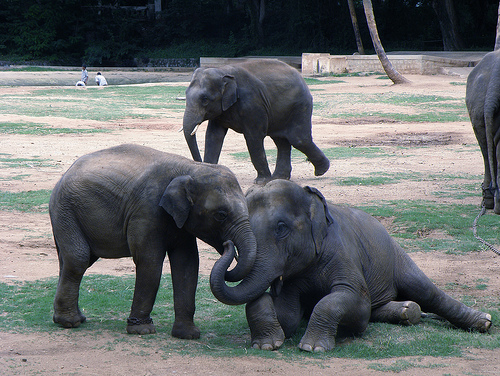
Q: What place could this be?
A: It is a field.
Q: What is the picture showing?
A: It is showing a field.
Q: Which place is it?
A: It is a field.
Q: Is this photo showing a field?
A: Yes, it is showing a field.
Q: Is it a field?
A: Yes, it is a field.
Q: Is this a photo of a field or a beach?
A: It is showing a field.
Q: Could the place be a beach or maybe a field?
A: It is a field.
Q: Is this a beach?
A: No, it is a field.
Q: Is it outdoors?
A: Yes, it is outdoors.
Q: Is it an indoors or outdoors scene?
A: It is outdoors.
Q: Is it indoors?
A: No, it is outdoors.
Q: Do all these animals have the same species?
A: Yes, all the animals are elephants.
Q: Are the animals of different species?
A: No, all the animals are elephants.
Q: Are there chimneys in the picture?
A: No, there are no chimneys.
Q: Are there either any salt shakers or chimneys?
A: No, there are no chimneys or salt shakers.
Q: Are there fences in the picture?
A: No, there are no fences.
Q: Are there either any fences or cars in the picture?
A: No, there are no fences or cars.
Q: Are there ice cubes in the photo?
A: No, there are no ice cubes.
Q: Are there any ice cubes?
A: No, there are no ice cubes.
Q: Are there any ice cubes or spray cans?
A: No, there are no ice cubes or spray cans.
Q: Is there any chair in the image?
A: No, there are no chairs.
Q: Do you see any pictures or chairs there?
A: No, there are no chairs or pictures.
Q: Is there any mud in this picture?
A: Yes, there is mud.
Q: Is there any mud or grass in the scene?
A: Yes, there is mud.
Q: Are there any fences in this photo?
A: No, there are no fences.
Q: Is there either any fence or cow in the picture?
A: No, there are no fences or cows.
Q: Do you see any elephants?
A: Yes, there are elephants.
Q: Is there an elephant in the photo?
A: Yes, there are elephants.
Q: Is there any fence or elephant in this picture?
A: Yes, there are elephants.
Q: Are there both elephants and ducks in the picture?
A: No, there are elephants but no ducks.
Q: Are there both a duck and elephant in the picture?
A: No, there are elephants but no ducks.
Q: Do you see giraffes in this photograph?
A: No, there are no giraffes.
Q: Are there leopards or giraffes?
A: No, there are no giraffes or leopards.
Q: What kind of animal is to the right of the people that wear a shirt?
A: The animals are elephants.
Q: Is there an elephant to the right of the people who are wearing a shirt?
A: Yes, there are elephants to the right of the people.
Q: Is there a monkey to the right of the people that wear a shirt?
A: No, there are elephants to the right of the people.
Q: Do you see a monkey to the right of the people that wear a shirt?
A: No, there are elephants to the right of the people.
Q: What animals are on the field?
A: The animals are elephants.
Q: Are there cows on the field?
A: No, there are elephants on the field.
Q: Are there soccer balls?
A: No, there are no soccer balls.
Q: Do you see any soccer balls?
A: No, there are no soccer balls.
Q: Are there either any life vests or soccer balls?
A: No, there are no soccer balls or life vests.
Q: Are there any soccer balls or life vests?
A: No, there are no soccer balls or life vests.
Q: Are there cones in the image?
A: No, there are no cones.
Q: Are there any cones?
A: No, there are no cones.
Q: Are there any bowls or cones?
A: No, there are no cones or bowls.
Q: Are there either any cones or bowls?
A: No, there are no cones or bowls.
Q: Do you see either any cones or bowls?
A: No, there are no cones or bowls.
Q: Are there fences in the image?
A: No, there are no fences.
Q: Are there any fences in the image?
A: No, there are no fences.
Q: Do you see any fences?
A: No, there are no fences.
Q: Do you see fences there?
A: No, there are no fences.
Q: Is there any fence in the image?
A: No, there are no fences.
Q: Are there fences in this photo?
A: No, there are no fences.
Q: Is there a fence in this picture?
A: No, there are no fences.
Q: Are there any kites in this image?
A: No, there are no kites.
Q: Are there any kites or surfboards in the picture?
A: No, there are no kites or surfboards.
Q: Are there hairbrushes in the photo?
A: No, there are no hairbrushes.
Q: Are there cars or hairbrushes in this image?
A: No, there are no hairbrushes or cars.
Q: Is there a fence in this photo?
A: No, there are no fences.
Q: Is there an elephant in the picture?
A: Yes, there is an elephant.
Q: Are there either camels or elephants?
A: Yes, there is an elephant.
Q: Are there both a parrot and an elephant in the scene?
A: No, there is an elephant but no parrots.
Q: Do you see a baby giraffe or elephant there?
A: Yes, there is a baby elephant.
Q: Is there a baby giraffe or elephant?
A: Yes, there is a baby elephant.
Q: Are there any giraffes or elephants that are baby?
A: Yes, the elephant is a baby.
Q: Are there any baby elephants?
A: Yes, there is a baby elephant.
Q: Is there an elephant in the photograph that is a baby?
A: Yes, there is an elephant that is a baby.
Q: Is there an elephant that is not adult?
A: Yes, there is an baby elephant.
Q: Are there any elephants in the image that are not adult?
A: Yes, there is an baby elephant.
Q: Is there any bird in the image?
A: No, there are no birds.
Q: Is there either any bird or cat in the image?
A: No, there are no birds or cats.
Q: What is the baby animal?
A: The animal is an elephant.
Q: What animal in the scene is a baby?
A: The animal is an elephant.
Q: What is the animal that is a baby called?
A: The animal is an elephant.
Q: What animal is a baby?
A: The animal is an elephant.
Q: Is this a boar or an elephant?
A: This is an elephant.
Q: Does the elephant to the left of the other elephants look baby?
A: Yes, the elephant is a baby.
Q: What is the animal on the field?
A: The animal is an elephant.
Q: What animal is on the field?
A: The animal is an elephant.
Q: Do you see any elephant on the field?
A: Yes, there is an elephant on the field.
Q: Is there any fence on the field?
A: No, there is an elephant on the field.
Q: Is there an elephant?
A: Yes, there are elephants.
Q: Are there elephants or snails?
A: Yes, there are elephants.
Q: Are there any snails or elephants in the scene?
A: Yes, there are elephants.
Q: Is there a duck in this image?
A: No, there are no ducks.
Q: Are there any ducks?
A: No, there are no ducks.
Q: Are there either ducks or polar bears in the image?
A: No, there are no ducks or polar bears.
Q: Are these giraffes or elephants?
A: These are elephants.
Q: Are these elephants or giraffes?
A: These are elephants.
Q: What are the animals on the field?
A: The animals are elephants.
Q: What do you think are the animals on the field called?
A: The animals are elephants.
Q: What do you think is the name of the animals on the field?
A: The animals are elephants.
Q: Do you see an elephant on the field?
A: Yes, there are elephants on the field.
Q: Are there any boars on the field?
A: No, there are elephants on the field.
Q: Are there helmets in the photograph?
A: No, there are no helmets.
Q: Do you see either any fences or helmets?
A: No, there are no helmets or fences.